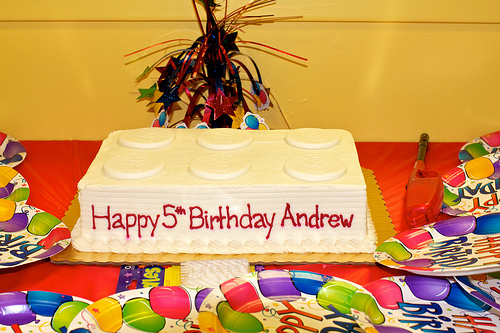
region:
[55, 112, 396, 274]
A kid's 5th birthday cake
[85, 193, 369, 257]
the text is made of frosting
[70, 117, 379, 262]
the cake is shaped like a rectangle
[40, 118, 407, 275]
the cake is on a piece of cardboard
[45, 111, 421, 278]
the cake is shaped like a Lego block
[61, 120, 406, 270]
white frosting covers the cake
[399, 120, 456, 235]
a red and black lighter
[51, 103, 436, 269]
this is a birthday cake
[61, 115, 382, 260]
the cake is a rectangle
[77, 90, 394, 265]
the cake is white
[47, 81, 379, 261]
this is a lego cake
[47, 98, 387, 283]
the cake is shaped like a lego block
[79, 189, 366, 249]
words in red frosting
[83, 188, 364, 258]
there is white and red frosting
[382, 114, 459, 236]
this is a lighter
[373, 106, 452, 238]
a red candle lighter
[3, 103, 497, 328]
there are colorful paper plates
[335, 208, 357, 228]
red letter on a white cake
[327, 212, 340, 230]
red letter on a white cake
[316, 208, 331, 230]
red letter on a white cake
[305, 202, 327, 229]
red letter on a white cake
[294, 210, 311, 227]
red letter on a white cake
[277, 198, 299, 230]
red letter on a white cake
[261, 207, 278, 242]
red letter on a white cake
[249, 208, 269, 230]
red letter on a white cake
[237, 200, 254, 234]
red letter on a white cake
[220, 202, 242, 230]
red letter on a white cake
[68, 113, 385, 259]
a white birthday cake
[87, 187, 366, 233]
red icing that says happy 5th birthday andrew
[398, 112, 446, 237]
a red and black bbq lighter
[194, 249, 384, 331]
paper happy birthday plate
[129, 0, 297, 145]
multi colored birthday streamers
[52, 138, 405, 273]
a silver cake tray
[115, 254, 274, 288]
a pack of white birthday candles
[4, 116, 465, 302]
a red table cloth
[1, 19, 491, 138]
a white wall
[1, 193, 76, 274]
a plate with balloons on it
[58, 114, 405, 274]
a white birthday cake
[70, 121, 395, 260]
a white birthday cake with red writing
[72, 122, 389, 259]
a Lego birthday cake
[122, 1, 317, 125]
a party decoration behind a cake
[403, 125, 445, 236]
a lighter on a table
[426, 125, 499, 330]
birthday cake plates on a table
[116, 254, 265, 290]
a package of candles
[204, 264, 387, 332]
a cake plates with balloon decorations on it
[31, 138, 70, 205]
an orange tablecloth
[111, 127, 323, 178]
white frosting on a cake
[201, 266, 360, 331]
a disposable party plate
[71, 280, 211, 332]
a party plate with balloon design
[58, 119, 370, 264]
a lego designed cake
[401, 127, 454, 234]
an extended electronic lighter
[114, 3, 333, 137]
a fountain made of foil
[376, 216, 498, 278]
a party plate with the words happy birthday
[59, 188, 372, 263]
a writing on the cake saying happy 5th birthday andrew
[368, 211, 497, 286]
a plate made for dining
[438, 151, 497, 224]
a plate made for dining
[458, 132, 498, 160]
a plate made for dining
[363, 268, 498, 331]
a plate made for dining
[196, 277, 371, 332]
a plate made for dining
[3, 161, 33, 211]
a plate made for dining